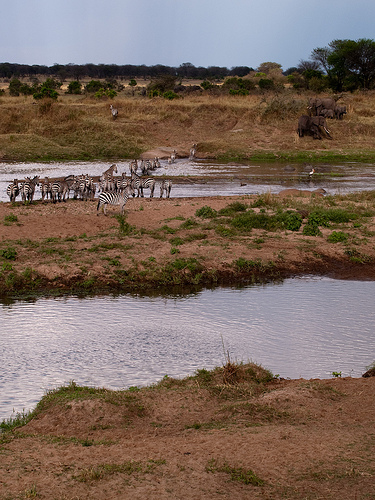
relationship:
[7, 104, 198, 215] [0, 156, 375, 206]
zebra crossing river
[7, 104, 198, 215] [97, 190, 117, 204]
zebra has stripes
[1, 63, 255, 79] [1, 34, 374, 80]
trees are on horizon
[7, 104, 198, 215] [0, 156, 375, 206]
zebra are in water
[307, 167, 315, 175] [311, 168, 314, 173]
bird has beak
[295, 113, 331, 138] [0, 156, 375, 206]
elephant near water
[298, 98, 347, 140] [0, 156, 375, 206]
elephant near water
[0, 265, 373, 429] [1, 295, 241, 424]
water has ripples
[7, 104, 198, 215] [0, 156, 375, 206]
zebra in water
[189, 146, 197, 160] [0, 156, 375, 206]
zebra in water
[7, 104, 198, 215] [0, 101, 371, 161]
zebra on hill